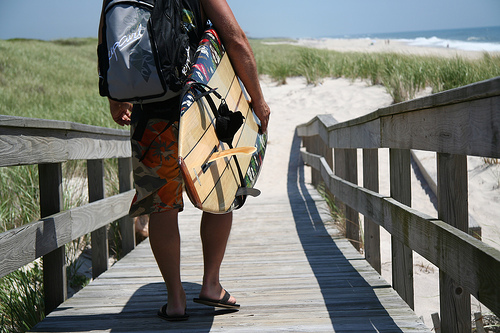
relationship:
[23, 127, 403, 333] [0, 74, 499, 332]
shadows on bridge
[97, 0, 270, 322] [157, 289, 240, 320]
man wearing slippers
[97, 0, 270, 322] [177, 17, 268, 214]
man carrying a surfboard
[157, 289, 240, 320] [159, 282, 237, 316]
slippers on mans feet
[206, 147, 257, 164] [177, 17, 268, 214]
fin on surfboard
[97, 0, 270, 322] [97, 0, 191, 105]
man carrying backpack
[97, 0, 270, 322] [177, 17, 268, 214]
man carrying surfboard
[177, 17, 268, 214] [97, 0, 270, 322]
surfboard held by man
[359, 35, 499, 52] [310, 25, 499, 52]
waves in water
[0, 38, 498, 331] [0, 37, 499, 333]
grass near sand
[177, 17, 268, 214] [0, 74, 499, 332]
surfboard above bridge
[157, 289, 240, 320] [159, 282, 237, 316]
slippers on feet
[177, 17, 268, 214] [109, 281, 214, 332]
surfboard making a shadow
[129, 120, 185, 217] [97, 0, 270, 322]
shorts on man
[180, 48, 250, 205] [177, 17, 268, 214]
black lines on surfboard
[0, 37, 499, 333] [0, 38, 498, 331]
sand near grass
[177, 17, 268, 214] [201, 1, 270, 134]
surfboard under right arm